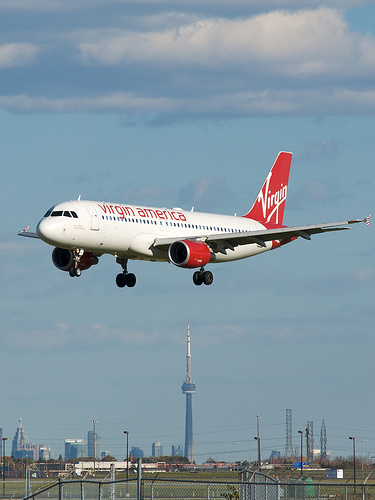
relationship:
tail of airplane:
[244, 152, 289, 224] [18, 150, 370, 288]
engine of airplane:
[165, 241, 211, 269] [18, 150, 370, 288]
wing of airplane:
[155, 216, 368, 257] [18, 150, 370, 288]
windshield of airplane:
[43, 208, 77, 220] [18, 150, 370, 288]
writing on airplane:
[96, 201, 188, 223] [18, 150, 370, 288]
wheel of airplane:
[112, 271, 136, 288] [18, 150, 370, 288]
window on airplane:
[100, 215, 106, 221] [18, 150, 370, 288]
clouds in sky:
[4, 0, 374, 121] [0, 0, 371, 459]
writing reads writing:
[96, 201, 188, 223] [96, 201, 188, 223]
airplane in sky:
[18, 150, 370, 288] [0, 0, 371, 459]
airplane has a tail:
[18, 150, 370, 288] [244, 152, 289, 224]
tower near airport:
[182, 323, 197, 458] [0, 469, 373, 498]